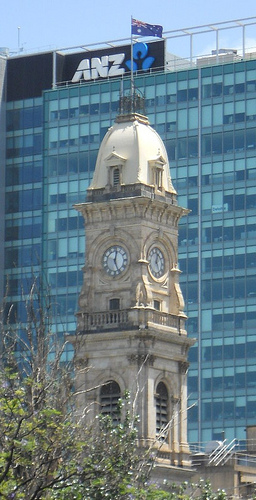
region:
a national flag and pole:
[129, 12, 161, 111]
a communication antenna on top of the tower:
[116, 74, 120, 110]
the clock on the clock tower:
[100, 245, 127, 277]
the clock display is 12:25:
[100, 245, 128, 277]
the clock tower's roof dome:
[86, 119, 177, 193]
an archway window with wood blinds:
[151, 371, 176, 448]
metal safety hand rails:
[185, 438, 254, 464]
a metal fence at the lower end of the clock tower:
[224, 482, 255, 498]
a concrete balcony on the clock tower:
[74, 306, 186, 334]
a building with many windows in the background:
[189, 60, 255, 440]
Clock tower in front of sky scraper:
[70, 78, 194, 497]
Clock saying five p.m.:
[78, 235, 137, 282]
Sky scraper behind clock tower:
[1, 2, 254, 454]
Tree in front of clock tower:
[2, 275, 255, 498]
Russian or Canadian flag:
[125, 12, 169, 127]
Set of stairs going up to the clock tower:
[202, 432, 242, 487]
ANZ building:
[58, 44, 178, 84]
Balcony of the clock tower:
[80, 304, 143, 330]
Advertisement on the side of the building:
[209, 205, 233, 210]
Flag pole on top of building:
[12, 16, 24, 54]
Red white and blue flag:
[129, 15, 163, 123]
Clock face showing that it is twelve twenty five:
[100, 244, 129, 278]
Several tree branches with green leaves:
[9, 397, 73, 487]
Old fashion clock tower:
[63, 86, 196, 486]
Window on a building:
[209, 335, 223, 366]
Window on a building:
[209, 397, 223, 426]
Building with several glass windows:
[212, 307, 247, 426]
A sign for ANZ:
[70, 53, 128, 82]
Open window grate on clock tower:
[150, 367, 172, 453]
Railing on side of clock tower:
[76, 311, 141, 329]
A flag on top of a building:
[129, 15, 164, 38]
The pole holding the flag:
[130, 35, 133, 92]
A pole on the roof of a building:
[16, 25, 20, 51]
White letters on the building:
[70, 51, 125, 82]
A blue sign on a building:
[124, 40, 156, 72]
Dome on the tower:
[84, 120, 178, 193]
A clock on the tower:
[99, 243, 132, 277]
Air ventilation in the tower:
[112, 166, 120, 186]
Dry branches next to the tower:
[28, 325, 48, 374]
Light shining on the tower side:
[145, 382, 156, 437]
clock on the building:
[91, 240, 182, 289]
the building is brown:
[65, 148, 182, 495]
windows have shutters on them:
[97, 380, 172, 438]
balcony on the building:
[74, 302, 197, 342]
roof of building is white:
[97, 123, 187, 199]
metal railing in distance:
[186, 432, 251, 467]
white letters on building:
[56, 49, 128, 87]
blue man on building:
[125, 37, 168, 71]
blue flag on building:
[109, 6, 174, 50]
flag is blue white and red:
[126, 6, 169, 48]